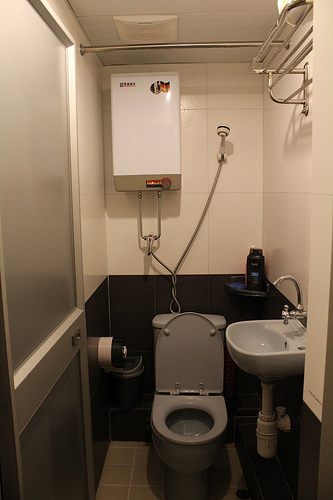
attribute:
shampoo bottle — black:
[243, 246, 266, 290]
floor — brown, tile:
[95, 437, 292, 498]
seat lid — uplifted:
[152, 312, 225, 396]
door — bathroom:
[4, 6, 89, 492]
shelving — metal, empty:
[240, 14, 317, 129]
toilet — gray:
[142, 297, 246, 473]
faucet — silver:
[268, 270, 307, 328]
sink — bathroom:
[225, 272, 310, 400]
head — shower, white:
[213, 116, 239, 167]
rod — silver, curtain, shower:
[77, 38, 294, 64]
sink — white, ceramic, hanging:
[224, 307, 309, 454]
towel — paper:
[98, 330, 126, 372]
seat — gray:
[152, 390, 224, 450]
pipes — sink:
[251, 383, 293, 457]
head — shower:
[212, 123, 234, 161]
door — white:
[9, 18, 105, 495]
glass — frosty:
[2, 21, 81, 327]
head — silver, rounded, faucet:
[270, 269, 306, 324]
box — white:
[105, 66, 186, 193]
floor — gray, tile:
[111, 448, 149, 498]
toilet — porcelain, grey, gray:
[149, 310, 226, 490]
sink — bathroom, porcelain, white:
[223, 306, 312, 376]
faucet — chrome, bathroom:
[267, 273, 307, 334]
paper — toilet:
[94, 325, 141, 372]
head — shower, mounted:
[213, 122, 236, 163]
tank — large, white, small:
[107, 65, 184, 194]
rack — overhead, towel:
[257, 1, 315, 114]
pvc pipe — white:
[254, 379, 292, 458]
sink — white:
[224, 314, 307, 384]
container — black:
[245, 245, 266, 292]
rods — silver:
[77, 0, 315, 118]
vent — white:
[112, 14, 180, 45]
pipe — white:
[255, 379, 294, 458]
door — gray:
[0, 0, 98, 498]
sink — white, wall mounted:
[226, 316, 313, 381]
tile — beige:
[101, 460, 134, 486]